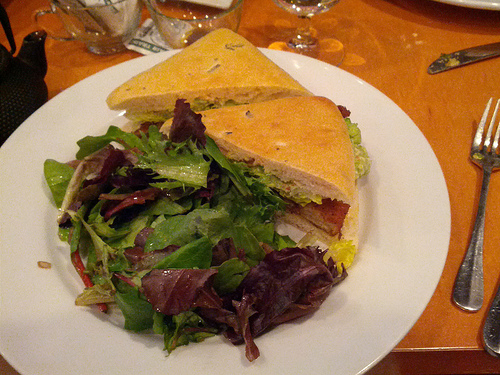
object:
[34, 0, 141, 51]
cup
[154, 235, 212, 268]
green lettuce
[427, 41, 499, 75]
knife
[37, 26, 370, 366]
food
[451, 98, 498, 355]
silverware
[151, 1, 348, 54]
glasses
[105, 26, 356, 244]
sandwich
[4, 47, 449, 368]
plate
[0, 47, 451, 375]
white plate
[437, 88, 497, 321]
tree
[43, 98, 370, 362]
leaves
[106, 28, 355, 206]
bread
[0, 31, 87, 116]
spout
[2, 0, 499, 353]
table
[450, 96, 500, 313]
fork